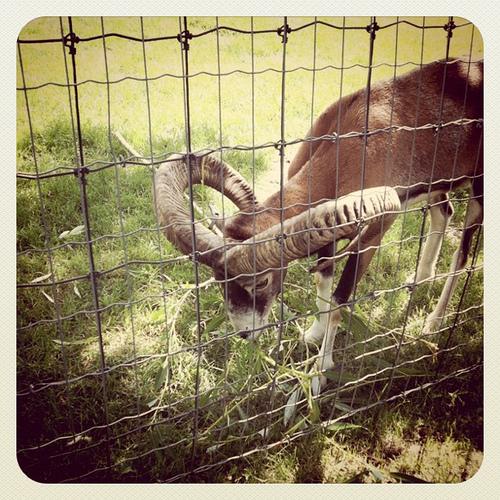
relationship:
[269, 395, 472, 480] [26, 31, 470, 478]
light shining on ground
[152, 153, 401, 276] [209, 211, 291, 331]
curved horns on top of head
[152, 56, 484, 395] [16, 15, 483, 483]
animal by fence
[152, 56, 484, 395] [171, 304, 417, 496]
animal eating plant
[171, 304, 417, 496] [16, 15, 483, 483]
plant by fence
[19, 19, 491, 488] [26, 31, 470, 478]
grass on ground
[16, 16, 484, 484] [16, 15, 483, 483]
fence on fence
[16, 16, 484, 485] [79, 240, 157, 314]
grass poking fence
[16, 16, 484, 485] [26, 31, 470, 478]
grass covering ground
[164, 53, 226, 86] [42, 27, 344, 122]
sun on grass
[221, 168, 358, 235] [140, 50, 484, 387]
animal's neck on animal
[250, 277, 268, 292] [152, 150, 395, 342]
eye on head